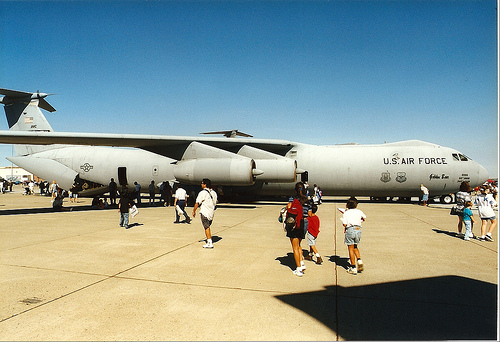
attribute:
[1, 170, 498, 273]
people — bunch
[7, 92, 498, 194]
plane — gray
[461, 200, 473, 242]
girl — small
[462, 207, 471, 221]
shirt —  blue 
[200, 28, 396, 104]
clouds — white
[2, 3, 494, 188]
sky — blue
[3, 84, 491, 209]
airplane — large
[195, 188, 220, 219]
shirt — white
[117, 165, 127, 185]
door — open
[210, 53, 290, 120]
clouds — white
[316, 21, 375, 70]
sky — blue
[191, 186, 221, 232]
attire — casual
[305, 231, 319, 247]
shorts — blue denim 